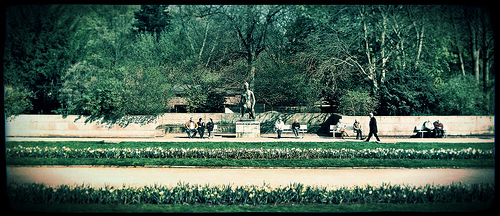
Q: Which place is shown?
A: It is a park.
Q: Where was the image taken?
A: It was taken at the park.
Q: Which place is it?
A: It is a park.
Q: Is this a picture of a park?
A: Yes, it is showing a park.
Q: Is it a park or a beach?
A: It is a park.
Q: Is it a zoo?
A: No, it is a park.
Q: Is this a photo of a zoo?
A: No, the picture is showing a park.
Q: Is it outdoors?
A: Yes, it is outdoors.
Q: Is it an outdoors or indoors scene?
A: It is outdoors.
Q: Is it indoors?
A: No, it is outdoors.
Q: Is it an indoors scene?
A: No, it is outdoors.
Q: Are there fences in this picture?
A: No, there are no fences.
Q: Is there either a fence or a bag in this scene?
A: No, there are no fences or bags.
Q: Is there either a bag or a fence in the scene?
A: No, there are no fences or bags.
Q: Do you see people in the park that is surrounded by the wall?
A: Yes, there are people in the park.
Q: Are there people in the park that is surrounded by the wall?
A: Yes, there are people in the park.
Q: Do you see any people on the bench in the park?
A: Yes, there are people on the bench.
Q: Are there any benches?
A: Yes, there is a bench.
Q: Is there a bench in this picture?
A: Yes, there is a bench.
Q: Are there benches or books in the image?
A: Yes, there is a bench.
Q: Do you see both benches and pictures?
A: No, there is a bench but no pictures.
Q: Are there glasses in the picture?
A: No, there are no glasses.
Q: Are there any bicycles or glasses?
A: No, there are no glasses or bicycles.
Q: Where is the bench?
A: The bench is in the park.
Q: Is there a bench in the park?
A: Yes, there is a bench in the park.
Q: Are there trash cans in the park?
A: No, there is a bench in the park.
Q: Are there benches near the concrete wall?
A: Yes, there is a bench near the wall.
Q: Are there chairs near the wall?
A: No, there is a bench near the wall.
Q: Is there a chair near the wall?
A: No, there is a bench near the wall.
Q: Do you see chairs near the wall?
A: No, there is a bench near the wall.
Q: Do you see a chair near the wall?
A: No, there is a bench near the wall.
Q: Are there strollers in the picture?
A: No, there are no strollers.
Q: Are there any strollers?
A: No, there are no strollers.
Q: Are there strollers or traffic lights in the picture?
A: No, there are no strollers or traffic lights.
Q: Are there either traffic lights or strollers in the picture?
A: No, there are no strollers or traffic lights.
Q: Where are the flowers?
A: The flowers are in the park.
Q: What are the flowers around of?
A: The flowers are around the pond.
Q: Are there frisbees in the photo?
A: No, there are no frisbees.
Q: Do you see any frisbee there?
A: No, there are no frisbees.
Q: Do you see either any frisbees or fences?
A: No, there are no frisbees or fences.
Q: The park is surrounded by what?
A: The park is surrounded by the wall.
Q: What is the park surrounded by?
A: The park is surrounded by the wall.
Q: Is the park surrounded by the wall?
A: Yes, the park is surrounded by the wall.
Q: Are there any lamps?
A: No, there are no lamps.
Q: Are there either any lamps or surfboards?
A: No, there are no lamps or surfboards.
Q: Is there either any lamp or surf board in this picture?
A: No, there are no lamps or surfboards.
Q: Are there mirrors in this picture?
A: No, there are no mirrors.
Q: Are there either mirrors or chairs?
A: No, there are no mirrors or chairs.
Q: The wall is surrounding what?
A: The wall is surrounding the park.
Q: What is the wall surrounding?
A: The wall is surrounding the park.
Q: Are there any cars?
A: No, there are no cars.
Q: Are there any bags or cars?
A: No, there are no cars or bags.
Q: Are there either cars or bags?
A: No, there are no cars or bags.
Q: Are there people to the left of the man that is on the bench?
A: Yes, there is a person to the left of the man.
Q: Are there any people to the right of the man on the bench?
A: No, the person is to the left of the man.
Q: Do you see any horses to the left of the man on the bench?
A: No, there is a person to the left of the man.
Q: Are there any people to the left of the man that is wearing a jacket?
A: Yes, there is a person to the left of the man.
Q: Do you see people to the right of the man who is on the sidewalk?
A: No, the person is to the left of the man.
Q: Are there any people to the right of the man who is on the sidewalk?
A: No, the person is to the left of the man.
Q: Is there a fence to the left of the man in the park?
A: No, there is a person to the left of the man.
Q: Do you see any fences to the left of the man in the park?
A: No, there is a person to the left of the man.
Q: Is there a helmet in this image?
A: No, there are no helmets.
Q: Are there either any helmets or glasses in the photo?
A: No, there are no helmets or glasses.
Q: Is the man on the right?
A: Yes, the man is on the right of the image.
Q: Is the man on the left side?
A: No, the man is on the right of the image.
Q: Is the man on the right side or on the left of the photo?
A: The man is on the right of the image.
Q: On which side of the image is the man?
A: The man is on the right of the image.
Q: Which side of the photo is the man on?
A: The man is on the right of the image.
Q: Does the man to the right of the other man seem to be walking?
A: Yes, the man is walking.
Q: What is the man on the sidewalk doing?
A: The man is walking.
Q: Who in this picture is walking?
A: The man is walking.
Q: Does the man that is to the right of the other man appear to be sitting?
A: No, the man is walking.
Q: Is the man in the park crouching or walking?
A: The man is walking.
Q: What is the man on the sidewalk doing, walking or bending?
A: The man is walking.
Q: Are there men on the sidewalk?
A: Yes, there is a man on the sidewalk.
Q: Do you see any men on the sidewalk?
A: Yes, there is a man on the sidewalk.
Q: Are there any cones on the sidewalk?
A: No, there is a man on the sidewalk.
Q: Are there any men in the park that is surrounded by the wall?
A: Yes, there is a man in the park.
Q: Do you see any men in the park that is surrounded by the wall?
A: Yes, there is a man in the park.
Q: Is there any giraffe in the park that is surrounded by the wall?
A: No, there is a man in the park.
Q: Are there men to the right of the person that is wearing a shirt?
A: Yes, there is a man to the right of the person.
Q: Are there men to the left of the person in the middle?
A: No, the man is to the right of the person.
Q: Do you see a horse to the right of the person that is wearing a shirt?
A: No, there is a man to the right of the person.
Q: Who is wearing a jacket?
A: The man is wearing a jacket.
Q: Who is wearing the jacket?
A: The man is wearing a jacket.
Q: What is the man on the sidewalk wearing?
A: The man is wearing a jacket.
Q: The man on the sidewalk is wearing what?
A: The man is wearing a jacket.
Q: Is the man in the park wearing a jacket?
A: Yes, the man is wearing a jacket.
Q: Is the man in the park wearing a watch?
A: No, the man is wearing a jacket.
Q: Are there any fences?
A: No, there are no fences.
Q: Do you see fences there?
A: No, there are no fences.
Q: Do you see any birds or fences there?
A: No, there are no fences or birds.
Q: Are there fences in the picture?
A: No, there are no fences.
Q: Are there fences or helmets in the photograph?
A: No, there are no fences or helmets.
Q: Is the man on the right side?
A: Yes, the man is on the right of the image.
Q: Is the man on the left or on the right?
A: The man is on the right of the image.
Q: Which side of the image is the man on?
A: The man is on the right of the image.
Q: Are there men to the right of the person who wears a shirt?
A: Yes, there is a man to the right of the person.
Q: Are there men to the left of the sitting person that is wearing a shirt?
A: No, the man is to the right of the person.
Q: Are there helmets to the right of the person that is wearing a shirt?
A: No, there is a man to the right of the person.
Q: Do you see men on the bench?
A: Yes, there is a man on the bench.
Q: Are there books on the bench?
A: No, there is a man on the bench.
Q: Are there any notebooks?
A: No, there are no notebooks.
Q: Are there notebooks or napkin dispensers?
A: No, there are no notebooks or napkin dispensers.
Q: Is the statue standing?
A: Yes, the statue is standing.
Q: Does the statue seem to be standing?
A: Yes, the statue is standing.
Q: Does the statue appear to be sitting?
A: No, the statue is standing.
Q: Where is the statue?
A: The statue is in the park.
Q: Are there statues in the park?
A: Yes, there is a statue in the park.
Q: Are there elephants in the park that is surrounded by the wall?
A: No, there is a statue in the park.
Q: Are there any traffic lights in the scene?
A: No, there are no traffic lights.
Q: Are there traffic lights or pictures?
A: No, there are no traffic lights or pictures.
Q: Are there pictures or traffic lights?
A: No, there are no traffic lights or pictures.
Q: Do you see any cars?
A: No, there are no cars.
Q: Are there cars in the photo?
A: No, there are no cars.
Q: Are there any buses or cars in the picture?
A: No, there are no cars or buses.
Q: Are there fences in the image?
A: No, there are no fences.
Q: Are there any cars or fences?
A: No, there are no fences or cars.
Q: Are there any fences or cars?
A: No, there are no fences or cars.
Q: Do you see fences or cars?
A: No, there are no fences or cars.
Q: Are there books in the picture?
A: No, there are no books.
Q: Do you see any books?
A: No, there are no books.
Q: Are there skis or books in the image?
A: No, there are no books or skis.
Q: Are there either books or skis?
A: No, there are no books or skis.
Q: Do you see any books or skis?
A: No, there are no books or skis.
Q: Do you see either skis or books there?
A: No, there are no books or skis.